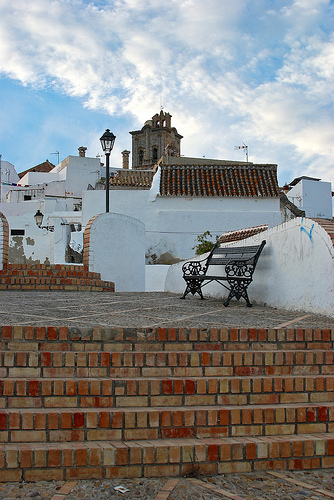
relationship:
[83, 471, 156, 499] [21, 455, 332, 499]
trash at bottom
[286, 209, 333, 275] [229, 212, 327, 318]
graffit on wall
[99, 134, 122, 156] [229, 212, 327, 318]
light by wall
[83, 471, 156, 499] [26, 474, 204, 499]
paper on ground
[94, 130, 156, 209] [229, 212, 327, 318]
lamp on wall